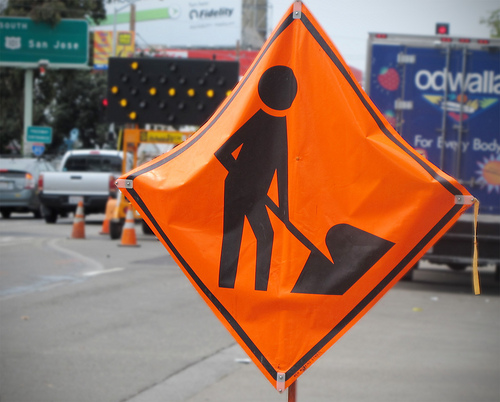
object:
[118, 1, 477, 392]
sign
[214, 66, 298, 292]
man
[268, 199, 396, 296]
shovel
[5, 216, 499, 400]
pavement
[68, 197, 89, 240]
cones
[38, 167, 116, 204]
back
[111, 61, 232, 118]
arrow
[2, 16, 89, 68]
sign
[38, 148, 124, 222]
cars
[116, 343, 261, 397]
scratch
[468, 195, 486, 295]
ribbon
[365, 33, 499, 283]
truck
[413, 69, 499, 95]
odwalla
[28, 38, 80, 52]
san jose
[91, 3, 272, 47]
banner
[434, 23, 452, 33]
light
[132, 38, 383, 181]
building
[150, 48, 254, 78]
roof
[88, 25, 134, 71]
billboard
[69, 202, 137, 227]
stripes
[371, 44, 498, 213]
back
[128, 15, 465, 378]
border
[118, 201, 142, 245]
cone